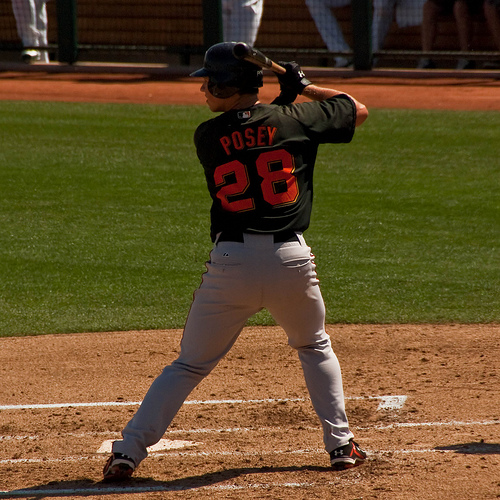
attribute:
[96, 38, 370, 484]
baseball player — preparing to bat, from sf giants, crouching to reduce, reducing strike zone, batting right, man, ready to swing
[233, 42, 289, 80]
baseball bat — black, wooden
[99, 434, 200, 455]
baseball plate — black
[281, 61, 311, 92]
glove — black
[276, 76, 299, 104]
glove — black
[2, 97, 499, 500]
field — grassy, immaculately kept, green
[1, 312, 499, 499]
patch of dirt — brown, holey, showing late innings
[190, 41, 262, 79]
baseball helmet — black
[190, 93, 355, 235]
baseball jersey — black, orange, inidicating visiting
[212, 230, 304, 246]
belt — black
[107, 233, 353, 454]
baseball pants — grey, gray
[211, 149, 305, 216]
number 28 — orange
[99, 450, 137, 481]
sneaker — black, white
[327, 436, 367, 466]
sneaker — orange